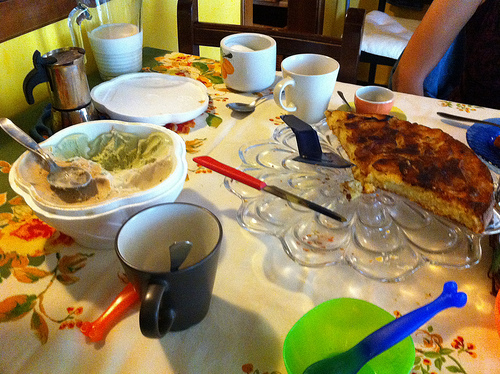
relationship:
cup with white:
[115, 200, 225, 342] [115, 201, 224, 274]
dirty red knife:
[266, 182, 347, 227] [192, 155, 348, 226]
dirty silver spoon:
[45, 162, 93, 191] [0, 116, 93, 190]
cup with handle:
[272, 53, 340, 126] [273, 76, 297, 117]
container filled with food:
[6, 117, 188, 252] [18, 125, 177, 213]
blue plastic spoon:
[300, 280, 468, 371] [0, 116, 93, 190]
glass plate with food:
[224, 117, 499, 287] [322, 108, 497, 236]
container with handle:
[21, 46, 99, 137] [21, 50, 58, 104]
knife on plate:
[192, 155, 348, 226] [224, 117, 499, 287]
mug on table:
[272, 53, 340, 126] [2, 44, 499, 373]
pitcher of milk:
[67, 0, 144, 82] [87, 22, 144, 82]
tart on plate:
[490, 132, 499, 161] [465, 116, 499, 172]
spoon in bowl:
[0, 116, 93, 190] [6, 117, 188, 252]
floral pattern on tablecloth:
[1, 45, 499, 374] [2, 45, 499, 372]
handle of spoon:
[168, 241, 194, 273] [167, 239, 193, 273]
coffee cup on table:
[272, 53, 340, 126] [2, 44, 499, 373]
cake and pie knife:
[322, 108, 497, 236] [281, 114, 356, 169]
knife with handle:
[192, 155, 348, 226] [192, 155, 268, 195]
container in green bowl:
[21, 46, 99, 137] [282, 297, 417, 373]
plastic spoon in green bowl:
[300, 280, 468, 371] [282, 297, 417, 373]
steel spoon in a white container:
[0, 116, 93, 190] [6, 117, 188, 252]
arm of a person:
[390, 0, 485, 106] [387, 0, 498, 110]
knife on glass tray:
[192, 155, 348, 226] [224, 117, 499, 287]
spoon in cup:
[167, 239, 193, 273] [115, 200, 225, 342]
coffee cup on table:
[115, 200, 225, 342] [2, 44, 499, 373]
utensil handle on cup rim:
[168, 241, 194, 273] [115, 201, 224, 274]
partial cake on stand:
[322, 108, 497, 236] [224, 117, 499, 287]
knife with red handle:
[192, 155, 348, 226] [192, 155, 268, 195]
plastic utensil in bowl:
[300, 280, 468, 371] [282, 297, 417, 373]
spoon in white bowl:
[0, 116, 93, 190] [6, 117, 188, 252]